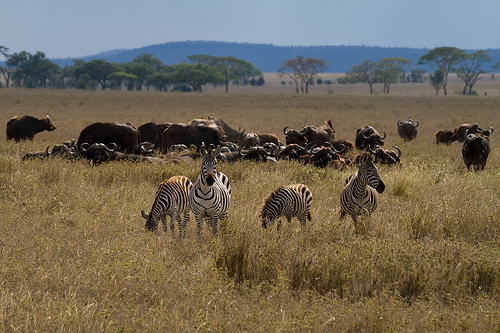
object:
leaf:
[158, 70, 161, 72]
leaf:
[192, 67, 193, 69]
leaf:
[103, 71, 107, 74]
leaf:
[119, 71, 124, 76]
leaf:
[151, 64, 153, 66]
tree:
[104, 69, 140, 92]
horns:
[380, 130, 390, 139]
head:
[361, 131, 390, 147]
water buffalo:
[353, 121, 387, 155]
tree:
[337, 60, 379, 95]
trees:
[414, 46, 466, 96]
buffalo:
[461, 124, 493, 172]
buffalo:
[393, 115, 421, 143]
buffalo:
[282, 124, 310, 147]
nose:
[373, 180, 387, 195]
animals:
[2, 111, 59, 147]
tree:
[278, 55, 328, 95]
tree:
[190, 54, 265, 96]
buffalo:
[138, 121, 170, 156]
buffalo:
[73, 120, 141, 163]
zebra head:
[351, 151, 389, 197]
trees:
[378, 55, 410, 96]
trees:
[408, 66, 428, 85]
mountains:
[0, 39, 500, 78]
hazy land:
[3, 38, 498, 73]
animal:
[339, 151, 386, 223]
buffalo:
[235, 144, 277, 164]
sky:
[2, 2, 498, 39]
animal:
[334, 156, 388, 231]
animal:
[258, 181, 318, 231]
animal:
[188, 141, 236, 237]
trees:
[450, 47, 499, 98]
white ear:
[197, 141, 209, 157]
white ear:
[210, 144, 226, 157]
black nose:
[204, 173, 219, 187]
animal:
[394, 115, 422, 143]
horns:
[361, 126, 373, 141]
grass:
[11, 243, 496, 320]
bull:
[353, 123, 389, 152]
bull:
[300, 117, 339, 144]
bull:
[75, 118, 139, 165]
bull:
[78, 140, 163, 166]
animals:
[139, 172, 194, 240]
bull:
[2, 107, 57, 145]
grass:
[0, 90, 500, 331]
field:
[0, 80, 500, 331]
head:
[256, 197, 282, 232]